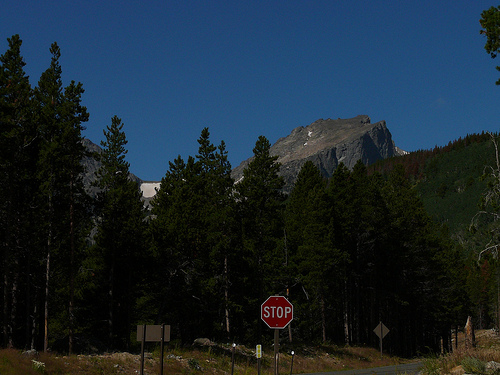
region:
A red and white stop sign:
[259, 293, 294, 332]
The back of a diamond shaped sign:
[372, 320, 389, 340]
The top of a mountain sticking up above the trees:
[226, 113, 399, 196]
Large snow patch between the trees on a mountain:
[139, 179, 161, 199]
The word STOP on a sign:
[261, 304, 291, 319]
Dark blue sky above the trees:
[1, 1, 499, 155]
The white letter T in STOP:
[268, 304, 275, 320]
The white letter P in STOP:
[283, 305, 290, 318]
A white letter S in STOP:
[263, 305, 269, 317]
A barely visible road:
[310, 360, 437, 373]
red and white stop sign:
[259, 291, 296, 328]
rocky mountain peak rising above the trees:
[233, 113, 400, 161]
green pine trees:
[1, 30, 463, 352]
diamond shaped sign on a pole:
[371, 317, 391, 362]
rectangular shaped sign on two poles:
[135, 321, 170, 373]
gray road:
[319, 355, 441, 373]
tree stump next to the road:
[458, 313, 477, 350]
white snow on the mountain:
[133, 180, 163, 198]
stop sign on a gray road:
[258, 289, 300, 374]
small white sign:
[253, 340, 261, 371]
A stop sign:
[259, 294, 293, 329]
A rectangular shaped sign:
[136, 323, 171, 342]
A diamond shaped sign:
[372, 323, 389, 340]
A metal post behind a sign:
[161, 323, 166, 374]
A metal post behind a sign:
[138, 323, 147, 373]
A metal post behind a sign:
[377, 322, 384, 356]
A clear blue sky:
[1, 1, 498, 181]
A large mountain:
[75, 113, 408, 204]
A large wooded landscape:
[0, 32, 499, 339]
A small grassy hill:
[0, 344, 410, 373]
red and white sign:
[255, 298, 290, 329]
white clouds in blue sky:
[70, 15, 100, 45]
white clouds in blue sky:
[82, 37, 136, 75]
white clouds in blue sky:
[135, 63, 176, 105]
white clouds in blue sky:
[127, 103, 166, 141]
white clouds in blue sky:
[183, 24, 266, 63]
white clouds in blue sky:
[232, 72, 283, 118]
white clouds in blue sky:
[313, 17, 385, 63]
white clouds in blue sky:
[388, 48, 445, 103]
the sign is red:
[238, 264, 310, 354]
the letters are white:
[260, 295, 297, 322]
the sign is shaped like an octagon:
[235, 264, 295, 338]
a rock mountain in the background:
[205, 84, 414, 207]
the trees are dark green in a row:
[12, 110, 443, 342]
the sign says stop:
[236, 280, 302, 330]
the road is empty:
[295, 301, 462, 371]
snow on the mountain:
[105, 150, 195, 210]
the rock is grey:
[200, 86, 410, 192]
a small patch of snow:
[280, 115, 325, 148]